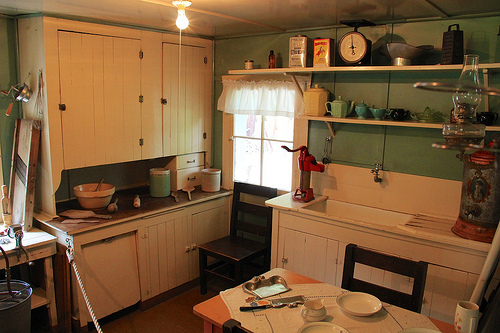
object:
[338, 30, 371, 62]
clock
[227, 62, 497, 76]
shelf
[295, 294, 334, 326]
pitcher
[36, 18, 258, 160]
wooden cabinets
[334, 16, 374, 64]
scale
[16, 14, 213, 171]
cabinet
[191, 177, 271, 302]
wooden chair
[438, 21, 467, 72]
grater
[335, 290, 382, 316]
plate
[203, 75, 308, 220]
window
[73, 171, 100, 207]
bowl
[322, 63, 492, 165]
walls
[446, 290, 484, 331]
mug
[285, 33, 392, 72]
items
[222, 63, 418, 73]
top shelf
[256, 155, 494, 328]
sink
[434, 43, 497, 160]
lamp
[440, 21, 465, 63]
cheese grater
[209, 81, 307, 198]
curtains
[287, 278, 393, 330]
bowls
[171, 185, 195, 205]
spoons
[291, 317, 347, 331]
plate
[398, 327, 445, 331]
plate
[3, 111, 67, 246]
mandoline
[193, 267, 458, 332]
table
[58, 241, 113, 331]
rope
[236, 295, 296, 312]
knife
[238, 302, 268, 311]
handle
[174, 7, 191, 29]
light bulb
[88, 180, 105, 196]
spoon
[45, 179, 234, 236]
counter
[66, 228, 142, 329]
cabinet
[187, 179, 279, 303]
chair